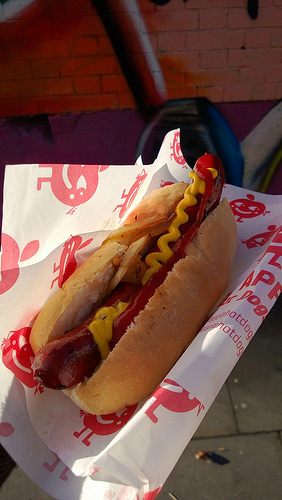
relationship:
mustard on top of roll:
[90, 167, 217, 365] [27, 148, 238, 420]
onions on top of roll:
[107, 234, 160, 289] [27, 148, 238, 420]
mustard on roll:
[90, 167, 217, 365] [27, 148, 238, 420]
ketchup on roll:
[113, 164, 212, 342] [27, 148, 238, 420]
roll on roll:
[27, 148, 238, 420] [27, 183, 240, 417]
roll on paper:
[27, 148, 238, 420] [0, 127, 281, 500]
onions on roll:
[107, 234, 160, 289] [27, 148, 238, 420]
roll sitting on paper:
[27, 148, 238, 420] [0, 127, 281, 500]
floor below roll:
[0, 298, 279, 499] [27, 148, 238, 420]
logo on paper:
[228, 191, 268, 226] [0, 127, 281, 500]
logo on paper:
[36, 163, 113, 212] [0, 127, 281, 500]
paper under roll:
[0, 127, 281, 500] [27, 148, 238, 420]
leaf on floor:
[194, 446, 224, 461] [0, 298, 279, 499]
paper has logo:
[0, 127, 281, 500] [228, 191, 268, 226]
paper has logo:
[0, 127, 281, 500] [36, 163, 113, 212]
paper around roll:
[0, 127, 281, 500] [27, 148, 238, 420]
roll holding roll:
[27, 183, 240, 417] [27, 148, 238, 420]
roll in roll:
[27, 148, 238, 420] [27, 183, 240, 417]